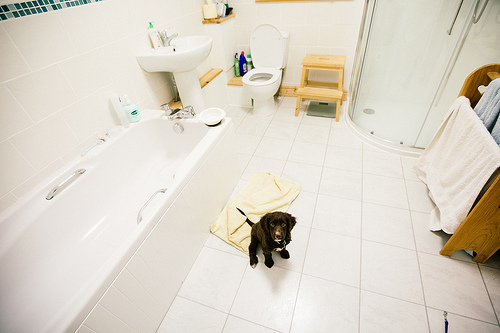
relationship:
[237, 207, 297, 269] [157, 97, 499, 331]
puppy sitting on floor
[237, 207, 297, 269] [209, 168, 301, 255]
puppy sitting on a towel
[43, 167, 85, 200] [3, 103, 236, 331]
handle on bathtub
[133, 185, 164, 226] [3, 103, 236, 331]
handle on bathtub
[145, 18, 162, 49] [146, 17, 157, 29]
bottle with a lid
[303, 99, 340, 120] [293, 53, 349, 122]
scale under step stool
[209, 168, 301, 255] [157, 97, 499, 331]
towel on floor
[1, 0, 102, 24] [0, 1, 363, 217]
tiles are on wall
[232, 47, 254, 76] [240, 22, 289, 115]
items are beside toilet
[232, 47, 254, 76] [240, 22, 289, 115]
items are next to toilet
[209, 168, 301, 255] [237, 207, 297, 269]
towel under puppy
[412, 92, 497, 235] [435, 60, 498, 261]
towel hanging on a rack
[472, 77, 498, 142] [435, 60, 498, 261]
towel hanging on a rack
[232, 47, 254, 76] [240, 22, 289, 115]
items next to toilet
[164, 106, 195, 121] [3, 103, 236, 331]
faucet on bathtub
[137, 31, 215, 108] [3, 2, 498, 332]
sink in bathroom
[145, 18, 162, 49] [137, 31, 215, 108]
hand soap on sink